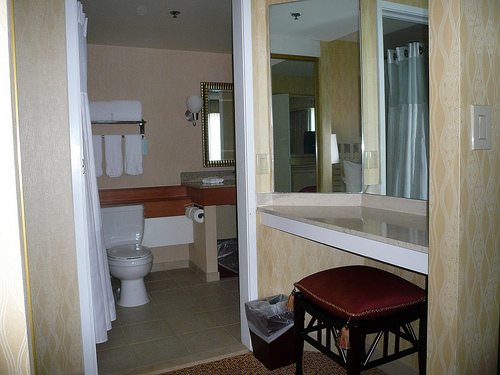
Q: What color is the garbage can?
A: Brown.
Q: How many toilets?
A: One.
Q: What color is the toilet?
A: White.